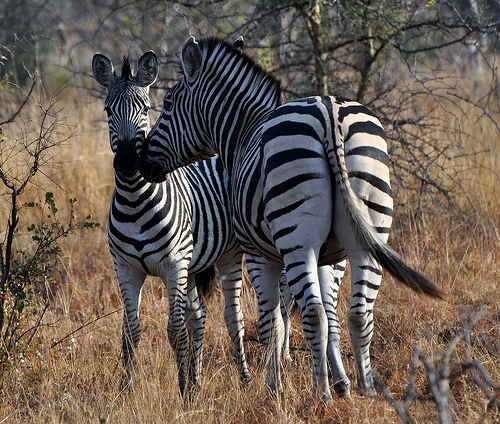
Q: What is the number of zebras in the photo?
A: Two.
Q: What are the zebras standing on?
A: Dried grass.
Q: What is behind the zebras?
A: Trees.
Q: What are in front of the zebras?
A: Twigs.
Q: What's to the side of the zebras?
A: Bush.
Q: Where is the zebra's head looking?
A: Straight forward.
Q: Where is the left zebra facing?
A: Forward.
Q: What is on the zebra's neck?
A: It's mane.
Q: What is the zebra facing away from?
A: The camera.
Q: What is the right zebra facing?
A: The camera.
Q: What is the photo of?
A: Zebras.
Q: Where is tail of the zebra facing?
A: Away from the camera.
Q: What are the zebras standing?
A: Grass.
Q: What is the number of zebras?
A: 2.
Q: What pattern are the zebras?
A: Striped.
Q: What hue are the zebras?
A: Black and white.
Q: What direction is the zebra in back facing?
A: Forward.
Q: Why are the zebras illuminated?
A: Sunny.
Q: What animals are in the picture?
A: Zebras.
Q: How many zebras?
A: Two.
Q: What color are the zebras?
A: Black and white.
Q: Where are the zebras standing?
A: Outdoors in a field.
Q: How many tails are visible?
A: One.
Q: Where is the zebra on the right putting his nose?
A: Next to the other zebra' nose.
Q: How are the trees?
A: Bare.